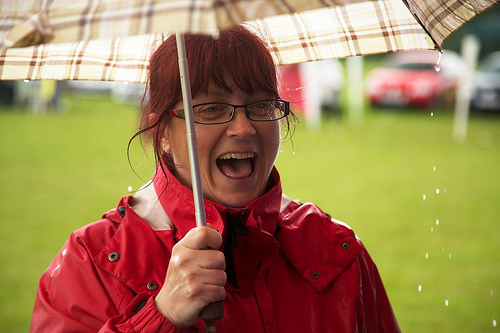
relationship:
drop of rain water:
[423, 109, 436, 115] [397, 41, 466, 330]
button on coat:
[105, 251, 123, 264] [29, 157, 399, 331]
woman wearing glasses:
[28, 26, 402, 331] [171, 96, 291, 127]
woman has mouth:
[28, 26, 402, 331] [212, 142, 261, 183]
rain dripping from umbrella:
[412, 49, 499, 331] [2, 0, 499, 226]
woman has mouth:
[28, 26, 402, 331] [209, 144, 265, 184]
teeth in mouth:
[216, 149, 259, 160] [209, 144, 265, 184]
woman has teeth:
[28, 26, 402, 331] [216, 149, 259, 160]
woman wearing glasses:
[28, 26, 402, 331] [164, 97, 293, 126]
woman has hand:
[28, 26, 402, 331] [154, 224, 230, 327]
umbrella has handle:
[2, 0, 499, 226] [174, 35, 206, 224]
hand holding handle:
[154, 224, 230, 327] [174, 35, 206, 224]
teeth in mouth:
[223, 152, 230, 159] [213, 146, 260, 183]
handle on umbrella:
[172, 33, 207, 226] [2, 0, 499, 226]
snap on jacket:
[105, 249, 121, 264] [32, 21, 403, 329]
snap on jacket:
[143, 278, 159, 294] [32, 21, 403, 329]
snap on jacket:
[303, 265, 326, 281] [32, 21, 403, 329]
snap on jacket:
[335, 235, 354, 248] [32, 21, 403, 329]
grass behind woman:
[0, 94, 499, 332] [28, 26, 402, 332]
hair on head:
[122, 21, 301, 196] [140, 28, 283, 212]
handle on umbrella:
[195, 297, 224, 330] [0, 0, 500, 329]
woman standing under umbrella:
[28, 26, 402, 331] [0, 0, 500, 329]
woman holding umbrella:
[28, 26, 402, 331] [0, 0, 500, 329]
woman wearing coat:
[28, 26, 402, 331] [29, 157, 400, 332]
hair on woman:
[121, 23, 298, 205] [28, 26, 402, 331]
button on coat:
[141, 275, 160, 291] [29, 157, 400, 332]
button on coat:
[309, 267, 325, 283] [29, 157, 400, 332]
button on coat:
[336, 235, 355, 250] [29, 157, 400, 332]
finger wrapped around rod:
[176, 223, 226, 245] [171, 30, 207, 227]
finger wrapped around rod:
[194, 248, 226, 269] [171, 30, 207, 227]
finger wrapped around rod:
[194, 262, 231, 289] [171, 30, 207, 227]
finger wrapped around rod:
[200, 280, 231, 304] [171, 30, 207, 227]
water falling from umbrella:
[415, 281, 425, 291] [0, 0, 500, 329]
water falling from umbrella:
[415, 280, 425, 291] [0, 0, 500, 329]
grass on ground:
[0, 94, 499, 332] [0, 85, 498, 326]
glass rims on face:
[164, 93, 292, 123] [164, 79, 280, 209]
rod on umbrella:
[171, 30, 208, 222] [0, 0, 500, 329]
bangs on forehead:
[165, 49, 277, 106] [164, 88, 280, 117]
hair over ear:
[121, 23, 298, 205] [145, 109, 170, 155]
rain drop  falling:
[447, 252, 455, 262] [394, 180, 454, 289]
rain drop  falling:
[447, 252, 455, 262] [402, 200, 481, 333]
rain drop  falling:
[447, 252, 455, 262] [404, 216, 493, 333]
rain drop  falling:
[447, 252, 455, 262] [374, 162, 490, 333]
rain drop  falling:
[447, 252, 455, 262] [420, 181, 473, 333]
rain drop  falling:
[447, 252, 455, 262] [411, 221, 464, 333]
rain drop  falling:
[412, 275, 423, 298] [399, 199, 499, 333]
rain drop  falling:
[447, 252, 455, 262] [395, 233, 497, 333]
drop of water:
[459, 317, 499, 332] [435, 255, 498, 333]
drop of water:
[485, 285, 498, 302] [472, 260, 498, 329]